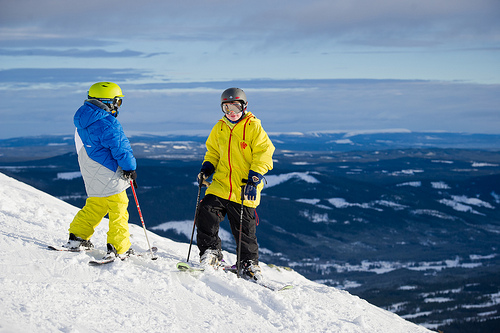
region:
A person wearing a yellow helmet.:
[71, 57, 126, 110]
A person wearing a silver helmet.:
[210, 80, 250, 105]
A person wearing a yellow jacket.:
[186, 106, 268, 214]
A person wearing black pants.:
[180, 190, 267, 261]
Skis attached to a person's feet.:
[166, 240, 302, 300]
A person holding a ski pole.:
[116, 173, 177, 278]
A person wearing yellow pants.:
[38, 177, 143, 264]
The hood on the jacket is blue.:
[63, 90, 108, 130]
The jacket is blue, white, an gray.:
[55, 85, 145, 200]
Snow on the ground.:
[25, 273, 229, 332]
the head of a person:
[217, 85, 256, 124]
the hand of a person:
[238, 161, 263, 203]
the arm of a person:
[248, 114, 278, 172]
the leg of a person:
[233, 193, 262, 267]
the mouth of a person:
[226, 109, 242, 121]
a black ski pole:
[224, 175, 254, 291]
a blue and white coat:
[71, 101, 138, 198]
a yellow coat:
[198, 112, 279, 210]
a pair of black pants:
[193, 189, 262, 278]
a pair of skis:
[43, 234, 137, 269]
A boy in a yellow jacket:
[173, 86, 295, 291]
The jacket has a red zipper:
[195, 85, 275, 202]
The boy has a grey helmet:
[201, 81, 271, 142]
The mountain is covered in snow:
[6, 130, 381, 320]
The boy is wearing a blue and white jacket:
[55, 65, 166, 260]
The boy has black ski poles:
[180, 160, 260, 285]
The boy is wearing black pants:
[185, 90, 290, 310]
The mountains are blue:
[90, 82, 484, 319]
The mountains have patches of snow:
[148, 132, 473, 309]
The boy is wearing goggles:
[68, 83, 144, 125]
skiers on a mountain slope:
[11, 7, 492, 323]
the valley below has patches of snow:
[12, 130, 499, 329]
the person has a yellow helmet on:
[84, 78, 124, 108]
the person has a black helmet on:
[221, 87, 248, 110]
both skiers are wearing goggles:
[108, 95, 243, 114]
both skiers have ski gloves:
[126, 162, 260, 204]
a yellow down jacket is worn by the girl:
[203, 113, 273, 208]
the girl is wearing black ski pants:
[196, 194, 258, 275]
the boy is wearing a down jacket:
[71, 102, 136, 200]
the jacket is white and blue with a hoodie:
[73, 102, 136, 200]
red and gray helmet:
[216, 76, 251, 111]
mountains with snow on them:
[281, 135, 441, 276]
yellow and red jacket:
[204, 117, 279, 223]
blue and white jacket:
[70, 108, 124, 200]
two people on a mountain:
[1, 69, 296, 298]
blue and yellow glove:
[236, 166, 274, 216]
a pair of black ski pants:
[169, 212, 276, 300]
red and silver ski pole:
[121, 161, 153, 286]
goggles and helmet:
[217, 92, 270, 125]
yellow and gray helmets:
[46, 77, 296, 129]